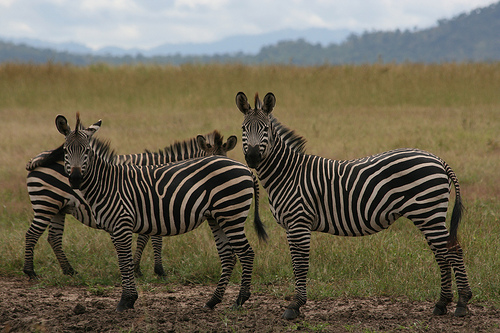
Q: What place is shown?
A: It is a plain.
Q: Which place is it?
A: It is a plain.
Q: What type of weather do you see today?
A: It is cloudy.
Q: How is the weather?
A: It is cloudy.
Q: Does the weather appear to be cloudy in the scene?
A: Yes, it is cloudy.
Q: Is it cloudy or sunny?
A: It is cloudy.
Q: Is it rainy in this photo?
A: No, it is cloudy.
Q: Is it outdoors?
A: Yes, it is outdoors.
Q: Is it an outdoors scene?
A: Yes, it is outdoors.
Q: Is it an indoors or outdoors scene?
A: It is outdoors.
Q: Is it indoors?
A: No, it is outdoors.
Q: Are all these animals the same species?
A: Yes, all the animals are zebras.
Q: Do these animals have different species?
A: No, all the animals are zebras.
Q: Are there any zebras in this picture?
A: Yes, there is a zebra.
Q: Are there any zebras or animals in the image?
A: Yes, there is a zebra.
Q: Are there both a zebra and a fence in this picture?
A: No, there is a zebra but no fences.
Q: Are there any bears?
A: No, there are no bears.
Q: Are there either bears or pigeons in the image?
A: No, there are no bears or pigeons.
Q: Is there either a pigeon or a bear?
A: No, there are no bears or pigeons.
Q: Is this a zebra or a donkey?
A: This is a zebra.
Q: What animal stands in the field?
A: The zebra stands in the field.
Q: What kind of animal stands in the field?
A: The animal is a zebra.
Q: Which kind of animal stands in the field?
A: The animal is a zebra.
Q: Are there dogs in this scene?
A: No, there are no dogs.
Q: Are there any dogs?
A: No, there are no dogs.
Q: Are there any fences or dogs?
A: No, there are no dogs or fences.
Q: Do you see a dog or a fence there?
A: No, there are no dogs or fences.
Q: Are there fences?
A: No, there are no fences.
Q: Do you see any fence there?
A: No, there are no fences.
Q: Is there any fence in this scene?
A: No, there are no fences.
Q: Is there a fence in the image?
A: No, there are no fences.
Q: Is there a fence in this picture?
A: No, there are no fences.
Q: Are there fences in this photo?
A: No, there are no fences.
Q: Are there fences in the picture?
A: No, there are no fences.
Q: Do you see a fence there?
A: No, there are no fences.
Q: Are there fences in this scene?
A: No, there are no fences.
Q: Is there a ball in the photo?
A: No, there are no balls.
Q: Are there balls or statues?
A: No, there are no balls or statues.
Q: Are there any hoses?
A: No, there are no hoses.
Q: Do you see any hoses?
A: No, there are no hoses.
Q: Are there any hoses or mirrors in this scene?
A: No, there are no hoses or mirrors.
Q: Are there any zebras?
A: Yes, there is a zebra.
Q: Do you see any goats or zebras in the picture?
A: Yes, there is a zebra.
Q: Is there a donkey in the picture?
A: No, there are no donkeys.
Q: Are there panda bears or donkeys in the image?
A: No, there are no donkeys or panda bears.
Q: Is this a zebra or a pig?
A: This is a zebra.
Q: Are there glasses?
A: No, there are no glasses.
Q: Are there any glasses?
A: No, there are no glasses.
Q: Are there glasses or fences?
A: No, there are no glasses or fences.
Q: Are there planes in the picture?
A: No, there are no planes.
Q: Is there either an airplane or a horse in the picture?
A: No, there are no airplanes or horses.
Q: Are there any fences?
A: No, there are no fences.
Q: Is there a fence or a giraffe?
A: No, there are no fences or giraffes.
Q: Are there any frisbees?
A: No, there are no frisbees.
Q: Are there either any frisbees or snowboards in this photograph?
A: No, there are no frisbees or snowboards.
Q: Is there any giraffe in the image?
A: No, there are no giraffes.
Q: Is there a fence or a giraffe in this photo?
A: No, there are no giraffes or fences.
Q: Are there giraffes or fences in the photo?
A: No, there are no giraffes or fences.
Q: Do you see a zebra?
A: Yes, there is a zebra.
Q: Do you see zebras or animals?
A: Yes, there is a zebra.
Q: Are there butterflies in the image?
A: No, there are no butterflies.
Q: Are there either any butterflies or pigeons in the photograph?
A: No, there are no butterflies or pigeons.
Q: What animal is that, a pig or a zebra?
A: That is a zebra.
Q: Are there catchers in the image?
A: No, there are no catchers.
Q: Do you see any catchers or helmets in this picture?
A: No, there are no catchers or helmets.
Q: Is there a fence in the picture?
A: No, there are no fences.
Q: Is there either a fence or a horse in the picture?
A: No, there are no fences or horses.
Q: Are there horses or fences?
A: No, there are no fences or horses.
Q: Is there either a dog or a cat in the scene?
A: No, there are no dogs or cats.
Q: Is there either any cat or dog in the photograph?
A: No, there are no dogs or cats.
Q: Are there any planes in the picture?
A: No, there are no planes.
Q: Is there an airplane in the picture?
A: No, there are no airplanes.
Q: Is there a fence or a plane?
A: No, there are no airplanes or fences.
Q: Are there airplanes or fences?
A: No, there are no airplanes or fences.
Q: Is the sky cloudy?
A: Yes, the sky is cloudy.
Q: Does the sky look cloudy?
A: Yes, the sky is cloudy.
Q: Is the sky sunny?
A: No, the sky is cloudy.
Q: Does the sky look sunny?
A: No, the sky is cloudy.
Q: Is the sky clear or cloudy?
A: The sky is cloudy.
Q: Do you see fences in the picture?
A: No, there are no fences.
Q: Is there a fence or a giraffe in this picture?
A: No, there are no fences or giraffes.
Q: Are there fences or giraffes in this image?
A: No, there are no fences or giraffes.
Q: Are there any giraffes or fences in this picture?
A: No, there are no fences or giraffes.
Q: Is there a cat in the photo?
A: No, there are no cats.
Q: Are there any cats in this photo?
A: No, there are no cats.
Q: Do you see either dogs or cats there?
A: No, there are no cats or dogs.